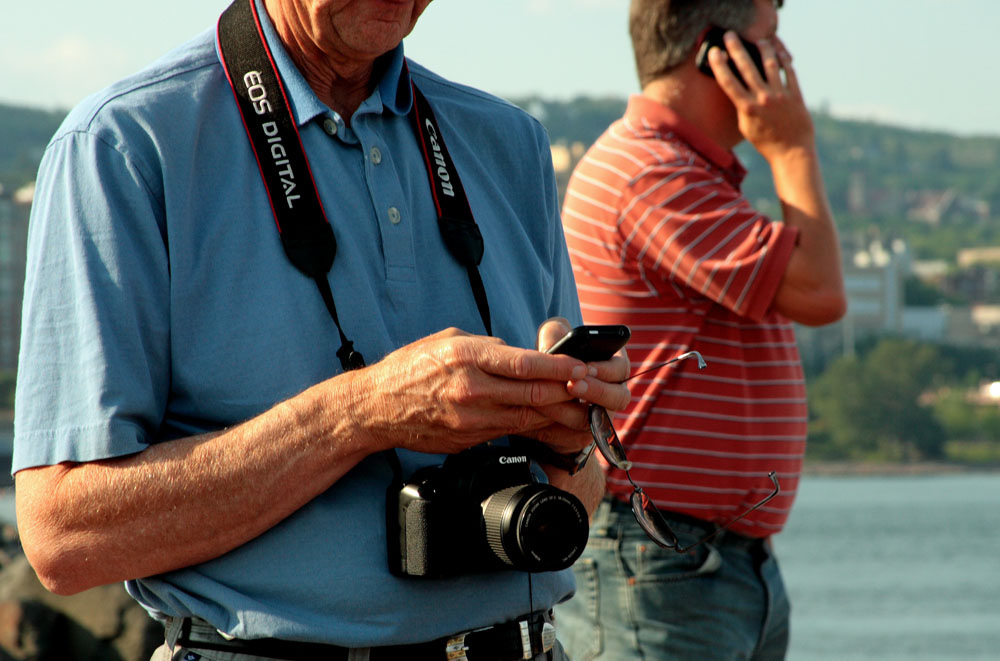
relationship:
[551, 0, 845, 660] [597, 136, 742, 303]
man has on shirt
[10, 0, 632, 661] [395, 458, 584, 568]
man has on camera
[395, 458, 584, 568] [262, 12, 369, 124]
camera around h neck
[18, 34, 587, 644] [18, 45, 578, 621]
man wearing shirt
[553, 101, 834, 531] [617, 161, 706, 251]
shirt with stripes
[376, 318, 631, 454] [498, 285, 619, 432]
hand holding cellphone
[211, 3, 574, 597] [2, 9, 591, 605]
strap hanging neck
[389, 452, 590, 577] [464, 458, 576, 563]
camera with lens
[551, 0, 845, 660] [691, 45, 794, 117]
man on cellphone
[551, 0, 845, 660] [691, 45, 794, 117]
man talking cellphone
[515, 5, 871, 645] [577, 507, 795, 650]
man wearing jeans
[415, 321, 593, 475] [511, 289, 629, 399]
hand holding glasses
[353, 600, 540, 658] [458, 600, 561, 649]
belt with buckle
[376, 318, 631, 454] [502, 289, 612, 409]
hand holding cellphone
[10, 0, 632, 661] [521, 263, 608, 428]
man holding cellphone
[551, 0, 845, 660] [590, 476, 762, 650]
man wearing jeans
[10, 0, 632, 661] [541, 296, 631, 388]
man holding cellphone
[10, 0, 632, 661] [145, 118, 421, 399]
man wearing shirt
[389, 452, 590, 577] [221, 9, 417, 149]
camera hanging from neck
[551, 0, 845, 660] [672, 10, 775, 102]
man talking on cellphone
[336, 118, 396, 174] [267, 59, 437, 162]
button on collar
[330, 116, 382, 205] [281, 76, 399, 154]
button on collar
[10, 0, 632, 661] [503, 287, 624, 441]
man holding phone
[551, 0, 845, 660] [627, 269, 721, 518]
man wearing shirt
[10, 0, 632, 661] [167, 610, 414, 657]
man wearing belt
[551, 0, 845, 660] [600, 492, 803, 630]
man wearing jeans